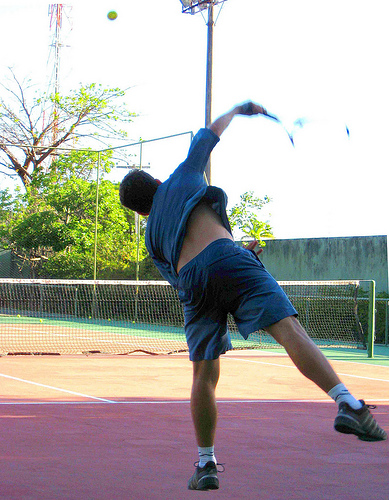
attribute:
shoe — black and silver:
[184, 457, 222, 493]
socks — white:
[312, 374, 382, 428]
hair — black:
[119, 167, 158, 212]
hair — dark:
[118, 175, 157, 205]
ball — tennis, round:
[106, 7, 119, 21]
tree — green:
[3, 72, 123, 204]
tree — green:
[15, 182, 143, 277]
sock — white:
[325, 383, 351, 404]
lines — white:
[0, 369, 385, 407]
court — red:
[29, 380, 386, 494]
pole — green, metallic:
[351, 279, 381, 319]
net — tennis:
[9, 254, 380, 387]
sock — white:
[326, 381, 364, 408]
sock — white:
[197, 444, 216, 465]